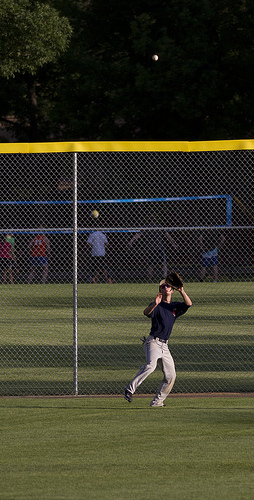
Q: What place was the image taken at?
A: It was taken at the park.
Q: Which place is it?
A: It is a park.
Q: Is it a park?
A: Yes, it is a park.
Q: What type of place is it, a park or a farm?
A: It is a park.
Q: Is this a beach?
A: No, it is a park.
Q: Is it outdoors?
A: Yes, it is outdoors.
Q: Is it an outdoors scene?
A: Yes, it is outdoors.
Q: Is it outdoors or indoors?
A: It is outdoors.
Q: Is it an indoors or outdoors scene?
A: It is outdoors.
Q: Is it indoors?
A: No, it is outdoors.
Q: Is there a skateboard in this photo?
A: No, there are no skateboards.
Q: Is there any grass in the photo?
A: Yes, there is grass.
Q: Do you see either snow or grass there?
A: Yes, there is grass.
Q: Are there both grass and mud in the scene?
A: No, there is grass but no mud.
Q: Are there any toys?
A: No, there are no toys.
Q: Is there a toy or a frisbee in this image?
A: No, there are no toys or frisbees.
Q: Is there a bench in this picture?
A: No, there are no benches.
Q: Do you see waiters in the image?
A: No, there are no waiters.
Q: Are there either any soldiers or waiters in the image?
A: No, there are no waiters or soldiers.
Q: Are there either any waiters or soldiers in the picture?
A: No, there are no waiters or soldiers.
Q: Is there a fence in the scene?
A: Yes, there is a fence.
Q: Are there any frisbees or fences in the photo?
A: Yes, there is a fence.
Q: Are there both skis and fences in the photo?
A: No, there is a fence but no skis.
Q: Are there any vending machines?
A: No, there are no vending machines.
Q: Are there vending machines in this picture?
A: No, there are no vending machines.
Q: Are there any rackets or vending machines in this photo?
A: No, there are no vending machines or rackets.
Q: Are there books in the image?
A: No, there are no books.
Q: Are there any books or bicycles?
A: No, there are no books or bicycles.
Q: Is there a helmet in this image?
A: No, there are no helmets.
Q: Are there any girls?
A: No, there are no girls.